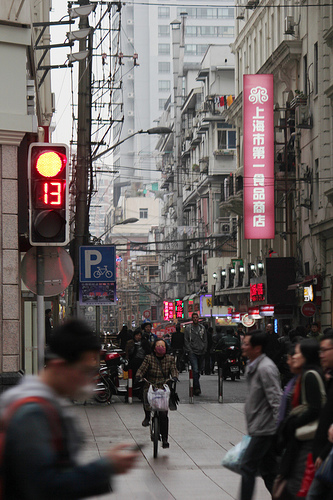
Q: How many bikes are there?
A: 1.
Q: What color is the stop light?
A: Yellow.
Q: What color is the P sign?
A: Blue.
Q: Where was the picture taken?
A: On a busy street.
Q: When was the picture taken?
A: In the day time.